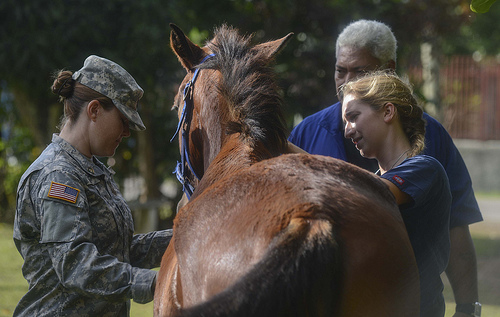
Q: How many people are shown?
A: 3.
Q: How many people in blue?
A: 2.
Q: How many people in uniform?
A: 1.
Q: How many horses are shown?
A: 1.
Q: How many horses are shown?
A: 1.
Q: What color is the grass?
A: Green.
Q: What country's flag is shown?
A: USA.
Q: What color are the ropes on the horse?
A: Blue.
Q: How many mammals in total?
A: 4.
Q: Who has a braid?
A: The woman.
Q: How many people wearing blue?
A: Two.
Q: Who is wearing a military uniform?
A: The woman.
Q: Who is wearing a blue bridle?
A: Brown horse.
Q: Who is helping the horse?
A: The young women.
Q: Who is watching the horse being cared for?
A: The older man.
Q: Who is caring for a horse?
A: The woman.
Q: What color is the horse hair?
A: Black and brown.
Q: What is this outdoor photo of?
A: People surrounding a horse.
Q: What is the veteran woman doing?
A: Standing.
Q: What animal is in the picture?
A: A horse.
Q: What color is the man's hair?
A: Gray.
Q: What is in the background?
A: Trees.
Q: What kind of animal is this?
A: A horse.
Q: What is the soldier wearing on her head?
A: A hat.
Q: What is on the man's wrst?
A: A watch.